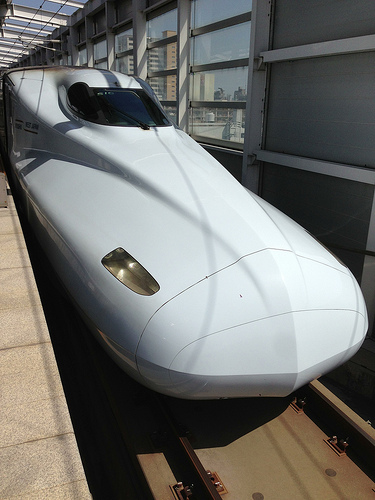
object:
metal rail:
[162, 405, 220, 499]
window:
[65, 81, 172, 130]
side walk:
[0, 166, 93, 500]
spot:
[299, 220, 374, 328]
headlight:
[304, 230, 347, 267]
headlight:
[100, 246, 160, 296]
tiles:
[0, 265, 51, 350]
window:
[144, 13, 170, 33]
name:
[15, 118, 39, 135]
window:
[190, 70, 250, 100]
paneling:
[260, 49, 375, 170]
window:
[114, 57, 134, 74]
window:
[187, 108, 245, 150]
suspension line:
[39, 6, 42, 31]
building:
[162, 29, 177, 109]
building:
[189, 72, 214, 100]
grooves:
[182, 378, 375, 500]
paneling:
[259, 161, 375, 253]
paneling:
[270, 2, 375, 50]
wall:
[263, 6, 362, 243]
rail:
[309, 377, 375, 446]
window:
[191, 0, 253, 28]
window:
[147, 74, 177, 101]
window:
[114, 28, 133, 54]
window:
[89, 42, 107, 67]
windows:
[189, 20, 251, 66]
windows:
[76, 42, 88, 66]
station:
[0, 10, 375, 499]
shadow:
[0, 87, 294, 499]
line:
[168, 309, 366, 399]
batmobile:
[2, 65, 369, 400]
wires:
[0, 7, 61, 70]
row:
[1, 0, 375, 145]